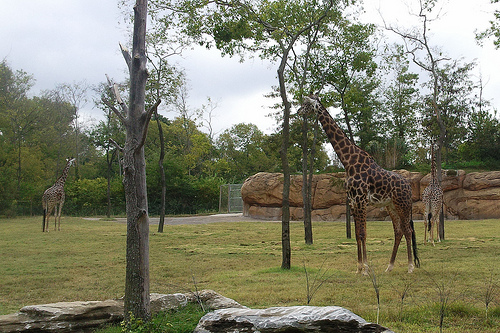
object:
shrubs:
[296, 251, 349, 312]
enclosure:
[0, 0, 500, 333]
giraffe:
[39, 157, 77, 232]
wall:
[242, 170, 500, 221]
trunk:
[265, 20, 300, 269]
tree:
[110, 4, 181, 323]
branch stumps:
[119, 41, 139, 71]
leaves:
[215, 20, 270, 43]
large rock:
[192, 305, 386, 332]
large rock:
[145, 288, 245, 310]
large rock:
[0, 300, 127, 333]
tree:
[125, 0, 159, 324]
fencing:
[227, 183, 248, 213]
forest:
[2, 54, 500, 218]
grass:
[0, 215, 499, 331]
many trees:
[87, 57, 183, 213]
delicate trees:
[0, 68, 56, 212]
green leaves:
[163, 139, 191, 150]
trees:
[387, 71, 427, 168]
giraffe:
[290, 97, 420, 277]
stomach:
[364, 189, 394, 210]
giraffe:
[420, 137, 444, 245]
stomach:
[431, 202, 442, 215]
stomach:
[51, 200, 60, 208]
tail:
[408, 209, 423, 269]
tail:
[425, 197, 433, 233]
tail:
[42, 198, 47, 233]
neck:
[315, 106, 356, 168]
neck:
[431, 150, 435, 178]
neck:
[57, 164, 72, 187]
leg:
[359, 201, 369, 268]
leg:
[352, 211, 362, 274]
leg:
[57, 204, 64, 231]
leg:
[53, 203, 58, 232]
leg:
[384, 208, 403, 273]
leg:
[395, 198, 416, 275]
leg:
[436, 200, 441, 244]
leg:
[422, 196, 430, 247]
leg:
[46, 201, 53, 232]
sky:
[0, 0, 499, 155]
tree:
[143, 0, 351, 274]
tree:
[379, 0, 460, 238]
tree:
[118, 11, 199, 236]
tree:
[40, 75, 95, 218]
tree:
[80, 81, 114, 217]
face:
[300, 103, 310, 114]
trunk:
[106, 1, 162, 324]